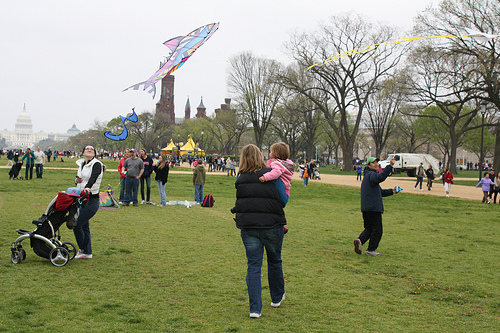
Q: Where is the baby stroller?
A: Left.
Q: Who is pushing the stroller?
A: Woman with white vest.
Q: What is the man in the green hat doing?
A: Flying a kite.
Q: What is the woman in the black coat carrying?
A: Baby girl.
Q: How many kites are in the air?
A: Three.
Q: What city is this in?
A: Washington D.C.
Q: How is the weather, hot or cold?
A: Cold.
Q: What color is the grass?
A: Green.